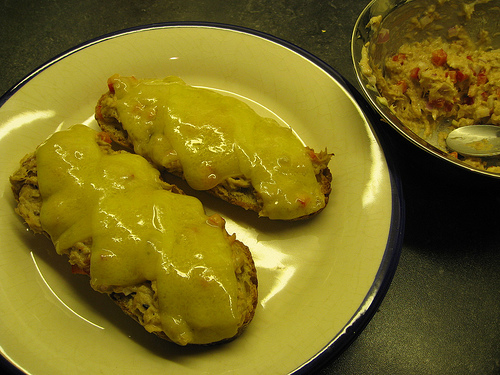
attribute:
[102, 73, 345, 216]
sandwich — open-faced, baked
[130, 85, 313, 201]
cheese — white, melted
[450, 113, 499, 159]
spoon — silver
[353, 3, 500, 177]
bowl — metal, silver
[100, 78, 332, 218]
bread — crusty, brown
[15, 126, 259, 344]
sandwich — crusty, baked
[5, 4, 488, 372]
surface — dark, black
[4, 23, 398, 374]
plate — white, round, black, yellow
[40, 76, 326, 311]
sauce — shining